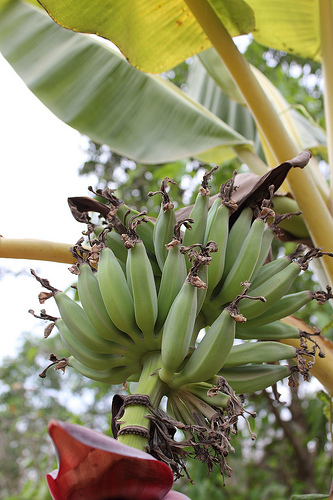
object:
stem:
[114, 354, 166, 453]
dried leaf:
[175, 147, 313, 223]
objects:
[199, 167, 218, 196]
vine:
[281, 316, 333, 394]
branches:
[149, 402, 246, 477]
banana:
[54, 195, 311, 396]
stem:
[0, 239, 88, 263]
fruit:
[55, 191, 313, 395]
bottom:
[108, 424, 156, 497]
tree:
[0, 0, 333, 500]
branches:
[195, 16, 333, 286]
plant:
[0, 0, 333, 500]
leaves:
[0, 335, 58, 500]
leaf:
[42, 417, 174, 498]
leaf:
[0, 0, 333, 162]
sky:
[0, 55, 90, 353]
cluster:
[53, 241, 237, 389]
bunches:
[27, 168, 332, 427]